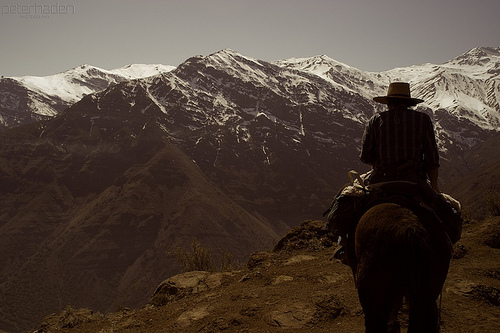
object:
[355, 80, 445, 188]
man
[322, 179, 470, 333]
horse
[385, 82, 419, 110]
head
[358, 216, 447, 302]
end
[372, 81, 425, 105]
cap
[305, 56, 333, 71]
snow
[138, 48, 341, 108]
mountain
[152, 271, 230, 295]
rock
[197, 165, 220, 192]
side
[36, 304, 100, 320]
grass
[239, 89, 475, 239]
scene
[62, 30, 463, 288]
background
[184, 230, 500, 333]
terrain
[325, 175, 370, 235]
bag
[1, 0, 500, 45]
sky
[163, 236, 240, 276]
brush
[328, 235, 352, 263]
foot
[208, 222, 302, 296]
cliff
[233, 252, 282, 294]
edge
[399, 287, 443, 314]
parts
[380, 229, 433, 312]
tail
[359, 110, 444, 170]
shirt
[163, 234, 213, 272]
plant